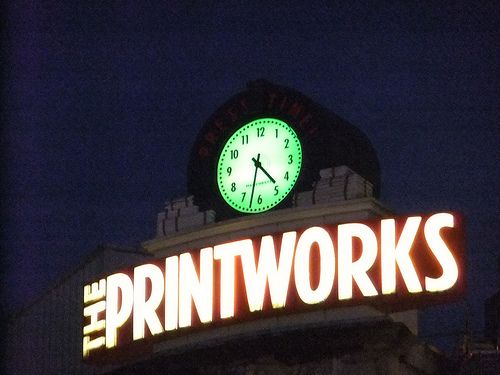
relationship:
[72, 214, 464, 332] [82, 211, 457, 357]
text on sign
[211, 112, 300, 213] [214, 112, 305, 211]
light on clock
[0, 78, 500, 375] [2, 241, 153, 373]
building of building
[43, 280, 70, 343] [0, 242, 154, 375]
cables of cables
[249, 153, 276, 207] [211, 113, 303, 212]
hand of clockface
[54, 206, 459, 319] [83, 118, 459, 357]
glow behind light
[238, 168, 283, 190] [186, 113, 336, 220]
letters on clock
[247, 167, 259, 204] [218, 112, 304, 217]
hand on clock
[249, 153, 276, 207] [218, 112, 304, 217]
hand on clock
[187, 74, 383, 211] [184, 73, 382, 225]
edge on clock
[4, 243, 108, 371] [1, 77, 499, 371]
side on building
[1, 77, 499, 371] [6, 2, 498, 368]
building in photo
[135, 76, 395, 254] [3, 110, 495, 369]
top to building